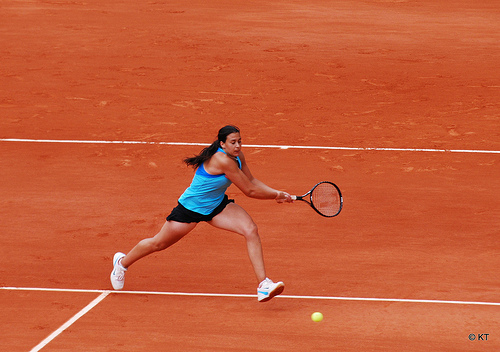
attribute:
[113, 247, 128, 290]
shoes — white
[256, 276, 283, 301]
shoes — white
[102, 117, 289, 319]
player — female, tennis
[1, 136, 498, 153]
line — white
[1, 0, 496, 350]
tennis court — white, black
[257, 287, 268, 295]
design — blue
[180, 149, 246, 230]
shirt — blue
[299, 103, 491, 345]
court — tennis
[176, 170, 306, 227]
shirt — blue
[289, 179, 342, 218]
racket — tennis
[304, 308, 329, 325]
ball — yellow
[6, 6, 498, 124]
tennis court — orange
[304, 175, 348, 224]
racket — tennis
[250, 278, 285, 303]
shoes — blue, white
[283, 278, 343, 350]
ball — tennis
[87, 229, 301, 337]
shoes — yellow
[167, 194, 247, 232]
skirt — black, short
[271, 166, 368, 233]
rackett — tennis